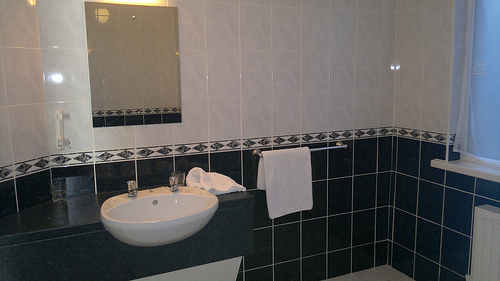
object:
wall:
[0, 1, 499, 281]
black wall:
[0, 137, 491, 281]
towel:
[184, 168, 247, 194]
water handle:
[126, 180, 138, 196]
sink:
[96, 185, 220, 248]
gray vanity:
[3, 188, 256, 280]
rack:
[242, 138, 351, 161]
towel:
[256, 146, 315, 221]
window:
[432, 0, 497, 186]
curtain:
[450, 0, 500, 166]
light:
[85, 0, 174, 7]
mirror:
[83, 1, 182, 129]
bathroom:
[0, 0, 495, 278]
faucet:
[167, 170, 186, 192]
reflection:
[87, 1, 181, 131]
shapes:
[266, 135, 292, 147]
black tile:
[3, 136, 499, 280]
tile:
[0, 0, 499, 281]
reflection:
[45, 71, 68, 87]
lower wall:
[0, 3, 499, 281]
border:
[0, 128, 462, 183]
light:
[46, 67, 71, 90]